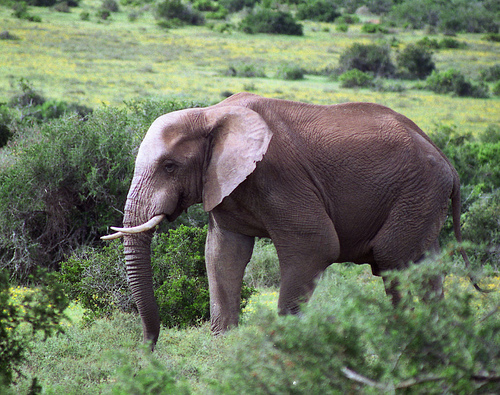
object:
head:
[111, 109, 213, 350]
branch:
[36, 187, 118, 262]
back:
[280, 101, 418, 146]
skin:
[279, 101, 428, 236]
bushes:
[424, 67, 467, 95]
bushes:
[337, 42, 394, 78]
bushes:
[297, 0, 343, 24]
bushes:
[234, 7, 304, 37]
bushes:
[152, 0, 209, 27]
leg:
[260, 189, 342, 315]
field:
[0, 0, 499, 144]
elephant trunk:
[122, 185, 160, 350]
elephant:
[100, 91, 497, 343]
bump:
[425, 153, 436, 162]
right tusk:
[98, 232, 129, 239]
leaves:
[30, 123, 61, 145]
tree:
[394, 44, 435, 79]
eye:
[162, 157, 180, 173]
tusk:
[110, 211, 166, 233]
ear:
[200, 106, 274, 211]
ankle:
[277, 296, 307, 315]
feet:
[278, 308, 303, 318]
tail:
[450, 167, 495, 297]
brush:
[9, 1, 44, 20]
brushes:
[0, 76, 223, 284]